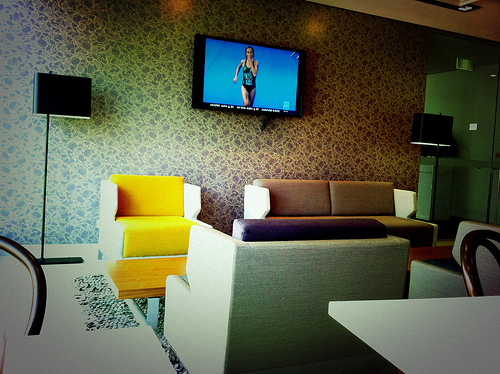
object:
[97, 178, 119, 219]
arm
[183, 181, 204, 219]
arm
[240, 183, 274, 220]
arm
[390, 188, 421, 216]
arm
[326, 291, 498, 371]
white table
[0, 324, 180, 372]
white table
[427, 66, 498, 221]
green armoire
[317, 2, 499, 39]
ceiling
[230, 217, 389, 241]
purple cushion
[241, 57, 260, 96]
swimsuit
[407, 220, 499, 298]
chair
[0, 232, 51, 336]
chair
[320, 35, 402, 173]
scales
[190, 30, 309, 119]
television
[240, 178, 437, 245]
loveseat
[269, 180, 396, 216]
fabric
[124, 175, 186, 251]
fabric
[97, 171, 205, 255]
chair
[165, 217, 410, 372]
chair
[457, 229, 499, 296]
chair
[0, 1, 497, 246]
wall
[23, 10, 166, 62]
wallpaper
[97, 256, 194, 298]
table top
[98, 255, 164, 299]
wood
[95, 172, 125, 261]
chair frame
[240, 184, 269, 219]
loveseat frame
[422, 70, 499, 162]
cabinets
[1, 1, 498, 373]
room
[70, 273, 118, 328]
rug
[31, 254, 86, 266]
base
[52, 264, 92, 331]
floor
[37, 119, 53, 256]
post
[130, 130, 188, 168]
wallpaper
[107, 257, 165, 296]
table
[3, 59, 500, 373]
furniture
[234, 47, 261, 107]
runner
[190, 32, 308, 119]
screen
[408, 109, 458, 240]
lamp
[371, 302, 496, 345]
item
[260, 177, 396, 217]
cushions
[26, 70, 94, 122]
box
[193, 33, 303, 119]
tv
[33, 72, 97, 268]
lamp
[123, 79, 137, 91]
spots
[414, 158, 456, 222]
boxes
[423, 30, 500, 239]
corner